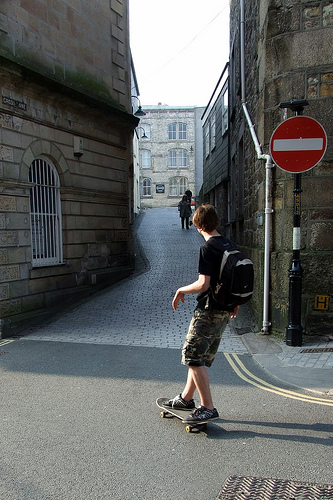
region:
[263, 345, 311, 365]
stone on side walk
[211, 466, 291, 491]
grate in the middle of the street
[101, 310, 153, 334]
cobble stone on the street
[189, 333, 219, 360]
green and brown cargo pants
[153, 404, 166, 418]
brown wheels on skate board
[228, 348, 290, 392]
yellow curved lines on side of road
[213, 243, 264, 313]
black back pack with white stripes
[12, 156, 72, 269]
white bars on window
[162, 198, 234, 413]
boy balancing on skate board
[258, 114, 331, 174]
large circular red and white sign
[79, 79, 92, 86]
Mould on the wall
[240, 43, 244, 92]
A drain pipe on the wall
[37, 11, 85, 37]
The surface of the wall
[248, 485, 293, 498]
A man hole lid on the street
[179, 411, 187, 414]
The surface of a roller skater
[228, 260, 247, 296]
A black back pack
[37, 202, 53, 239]
Grills on the window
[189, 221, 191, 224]
A woman holding a bag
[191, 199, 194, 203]
A red car in the background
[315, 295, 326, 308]
A fire hydrant sign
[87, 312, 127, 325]
A brick walk way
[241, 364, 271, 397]
Yellow lines on street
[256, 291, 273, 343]
White drain next to wall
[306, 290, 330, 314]
Yellow and back letter H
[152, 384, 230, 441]
Boy standing on skate board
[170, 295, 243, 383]
Boy wearing green pants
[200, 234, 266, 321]
Boy wearing black pack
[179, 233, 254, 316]
Boy wearing dark shirt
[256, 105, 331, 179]
Red and white do not enter sign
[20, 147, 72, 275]
White metal bars on window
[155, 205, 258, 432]
young male with backpack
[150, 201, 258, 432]
boy riding a skateboard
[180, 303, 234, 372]
pair of shorts with camo pattern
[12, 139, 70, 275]
arched window with white bars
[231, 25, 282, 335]
white drainage pipe on building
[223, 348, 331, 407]
double yellow lines on road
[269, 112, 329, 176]
red sign with white line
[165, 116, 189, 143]
double window with arch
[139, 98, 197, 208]
stone building with green roof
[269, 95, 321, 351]
black post with red sign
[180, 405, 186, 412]
part of a board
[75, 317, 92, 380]
part of a road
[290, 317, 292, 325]
part of a post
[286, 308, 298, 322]
part of a wall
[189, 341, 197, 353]
part of a short